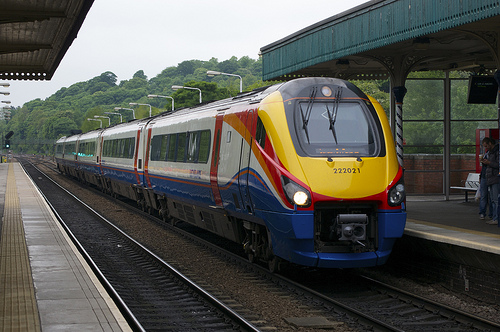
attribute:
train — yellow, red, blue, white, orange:
[144, 63, 423, 272]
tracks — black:
[183, 278, 409, 320]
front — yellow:
[262, 64, 419, 265]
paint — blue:
[285, 215, 305, 241]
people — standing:
[466, 130, 498, 228]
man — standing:
[480, 134, 498, 230]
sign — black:
[466, 68, 495, 109]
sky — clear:
[149, 5, 208, 40]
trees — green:
[78, 67, 153, 91]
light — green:
[3, 142, 14, 152]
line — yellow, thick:
[443, 220, 474, 236]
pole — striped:
[389, 84, 413, 129]